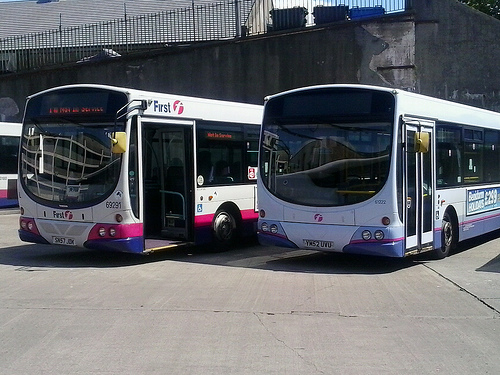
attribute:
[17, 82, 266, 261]
bus — red, white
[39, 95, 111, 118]
destination sign — electronic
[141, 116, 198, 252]
bus door — open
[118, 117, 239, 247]
doors — white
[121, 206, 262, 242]
stripe — red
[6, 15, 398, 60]
railing — black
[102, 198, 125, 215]
numbers — black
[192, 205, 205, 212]
handicap sign — blue